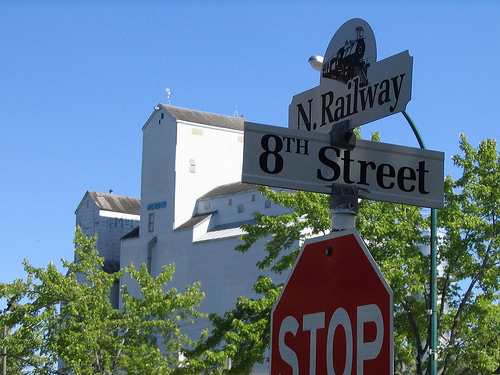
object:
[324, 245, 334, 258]
metal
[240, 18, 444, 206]
signs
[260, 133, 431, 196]
letters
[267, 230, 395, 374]
sign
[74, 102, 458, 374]
building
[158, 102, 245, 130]
roof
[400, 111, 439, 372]
pole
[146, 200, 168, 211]
label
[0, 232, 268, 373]
trees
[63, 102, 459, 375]
factory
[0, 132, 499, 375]
tree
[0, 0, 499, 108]
sky